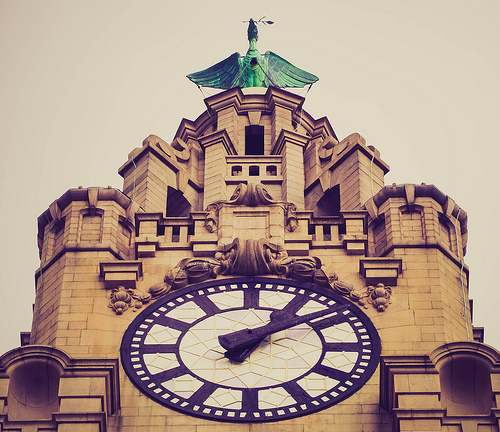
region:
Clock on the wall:
[152, 269, 394, 430]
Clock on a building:
[148, 253, 429, 425]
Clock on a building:
[119, 285, 357, 402]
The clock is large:
[85, 258, 382, 418]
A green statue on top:
[198, 20, 300, 95]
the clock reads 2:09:
[150, 243, 399, 429]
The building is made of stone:
[60, 150, 436, 385]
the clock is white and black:
[107, 281, 370, 430]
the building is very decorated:
[66, 173, 454, 275]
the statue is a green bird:
[175, 26, 340, 91]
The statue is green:
[181, 13, 325, 87]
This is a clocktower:
[67, 175, 424, 408]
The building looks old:
[12, 117, 438, 385]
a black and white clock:
[123, 275, 387, 421]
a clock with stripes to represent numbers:
[118, 276, 382, 421]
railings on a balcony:
[133, 206, 369, 251]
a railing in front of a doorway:
[227, 151, 286, 182]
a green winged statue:
[189, 21, 321, 91]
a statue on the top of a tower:
[185, 37, 318, 92]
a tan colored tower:
[34, 91, 469, 430]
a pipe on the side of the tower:
[360, 143, 378, 194]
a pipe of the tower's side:
[120, 157, 145, 203]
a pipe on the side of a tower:
[31, 209, 48, 342]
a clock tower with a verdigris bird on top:
[6, 12, 498, 430]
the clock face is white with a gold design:
[119, 276, 381, 422]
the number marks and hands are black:
[123, 277, 380, 419]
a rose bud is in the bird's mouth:
[236, 12, 277, 62]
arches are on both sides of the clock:
[3, 340, 498, 427]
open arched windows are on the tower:
[158, 123, 344, 245]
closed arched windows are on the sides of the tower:
[41, 199, 468, 269]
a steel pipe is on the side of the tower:
[451, 200, 477, 339]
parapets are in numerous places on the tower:
[11, 85, 496, 430]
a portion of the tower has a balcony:
[138, 198, 365, 256]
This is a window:
[74, 199, 107, 248]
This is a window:
[44, 216, 68, 258]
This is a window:
[113, 209, 135, 258]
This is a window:
[236, 111, 266, 160]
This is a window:
[366, 206, 393, 255]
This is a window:
[396, 199, 424, 246]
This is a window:
[433, 200, 463, 252]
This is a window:
[170, 219, 182, 244]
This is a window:
[152, 216, 172, 249]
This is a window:
[246, 162, 262, 178]